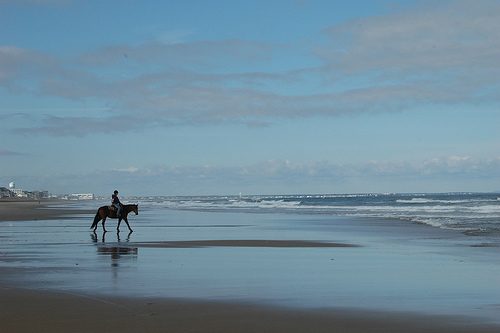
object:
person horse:
[89, 189, 141, 235]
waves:
[250, 197, 313, 208]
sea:
[158, 195, 238, 211]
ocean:
[369, 191, 443, 225]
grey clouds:
[0, 41, 83, 138]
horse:
[90, 203, 139, 232]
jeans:
[113, 203, 122, 217]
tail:
[90, 212, 101, 229]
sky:
[0, 0, 500, 200]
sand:
[0, 198, 499, 332]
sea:
[250, 194, 326, 214]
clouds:
[394, 24, 476, 110]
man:
[109, 190, 124, 218]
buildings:
[0, 180, 56, 199]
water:
[103, 246, 134, 253]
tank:
[5, 176, 27, 198]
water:
[353, 194, 392, 206]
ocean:
[438, 192, 499, 236]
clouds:
[258, 42, 326, 118]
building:
[68, 193, 96, 201]